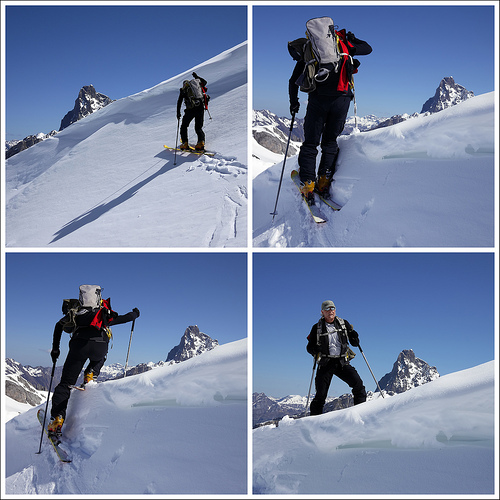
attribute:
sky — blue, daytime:
[102, 15, 139, 47]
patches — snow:
[344, 86, 482, 144]